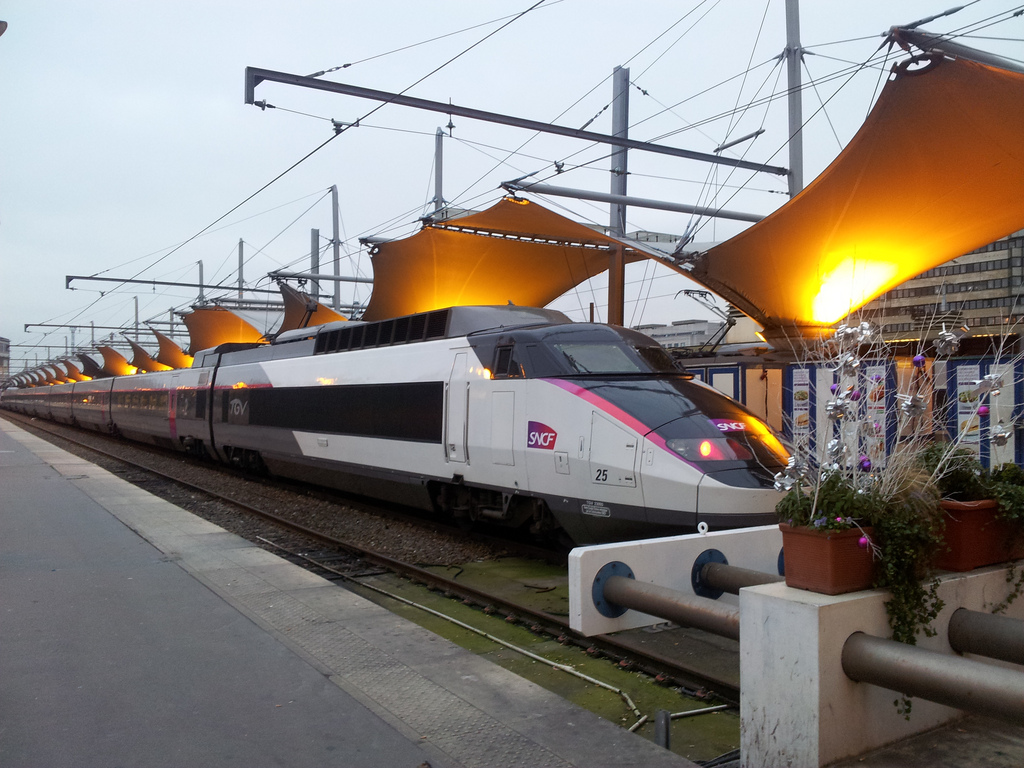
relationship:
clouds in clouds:
[170, 70, 283, 170] [0, 0, 1024, 386]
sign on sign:
[526, 419, 556, 450] [515, 408, 563, 454]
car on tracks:
[0, 302, 832, 551] [274, 523, 795, 658]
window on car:
[477, 316, 683, 386] [0, 302, 832, 551]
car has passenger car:
[0, 302, 832, 551] [107, 354, 218, 484]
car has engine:
[0, 302, 832, 551] [209, 288, 814, 567]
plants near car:
[775, 467, 910, 526] [0, 302, 832, 551]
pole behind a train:
[598, 55, 648, 345] [104, 312, 859, 563]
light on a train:
[689, 424, 737, 474] [300, 270, 806, 593]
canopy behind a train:
[343, 158, 653, 379] [75, 312, 979, 691]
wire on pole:
[654, 78, 745, 130] [765, 1, 837, 241]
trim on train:
[516, 318, 772, 498] [160, 270, 904, 614]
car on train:
[0, 302, 832, 551] [71, 279, 784, 627]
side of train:
[265, 324, 553, 474] [60, 297, 866, 615]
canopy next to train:
[2, 56, 1023, 412] [93, 320, 817, 558]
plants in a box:
[775, 312, 1024, 721] [754, 502, 960, 608]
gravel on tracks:
[293, 493, 402, 560] [188, 459, 552, 704]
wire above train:
[0, 0, 1024, 389] [52, 257, 854, 733]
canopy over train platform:
[2, 56, 1023, 412] [75, 242, 789, 748]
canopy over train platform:
[136, 270, 314, 385] [21, 318, 922, 764]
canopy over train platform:
[142, 290, 328, 390] [32, 340, 983, 749]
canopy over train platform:
[65, 296, 137, 379] [64, 286, 1002, 744]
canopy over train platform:
[91, 324, 148, 385] [36, 307, 950, 744]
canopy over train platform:
[58, 331, 132, 401] [60, 325, 648, 760]